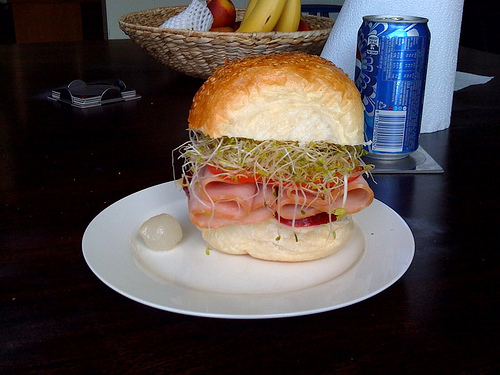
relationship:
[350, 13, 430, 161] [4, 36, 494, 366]
can on table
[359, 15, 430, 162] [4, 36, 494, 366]
cola on table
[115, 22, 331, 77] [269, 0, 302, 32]
basket of banana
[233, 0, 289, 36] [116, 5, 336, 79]
banana in basket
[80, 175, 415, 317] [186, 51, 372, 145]
plate for bun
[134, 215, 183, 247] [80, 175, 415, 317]
pearl onion on plate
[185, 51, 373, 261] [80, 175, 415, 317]
sandwhich on plate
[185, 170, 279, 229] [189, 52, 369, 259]
meat on sandwich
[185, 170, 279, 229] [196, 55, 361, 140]
meat on bun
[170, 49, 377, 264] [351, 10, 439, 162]
sandwhich with soda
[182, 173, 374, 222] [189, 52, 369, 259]
meat in sandwich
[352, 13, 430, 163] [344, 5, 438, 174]
cola in can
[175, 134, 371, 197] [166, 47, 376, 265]
sprouts on sandwich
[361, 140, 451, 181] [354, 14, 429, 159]
coaster under can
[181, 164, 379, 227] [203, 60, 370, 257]
meat in sandwich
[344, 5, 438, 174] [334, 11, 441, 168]
can has soda